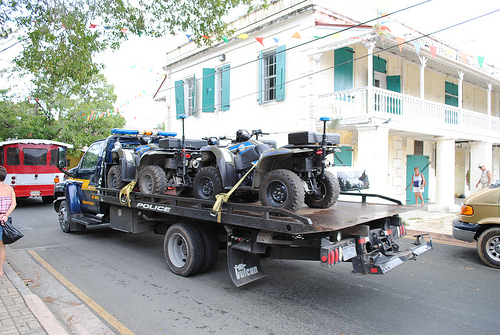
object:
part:
[177, 232, 191, 262]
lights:
[111, 128, 178, 137]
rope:
[211, 161, 259, 223]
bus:
[0, 138, 73, 204]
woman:
[0, 165, 22, 275]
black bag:
[2, 222, 24, 244]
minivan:
[447, 181, 500, 269]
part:
[406, 129, 426, 143]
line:
[23, 250, 134, 335]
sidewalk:
[0, 265, 66, 335]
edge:
[3, 251, 59, 330]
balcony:
[316, 53, 500, 142]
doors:
[202, 64, 230, 114]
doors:
[258, 44, 286, 105]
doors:
[174, 73, 196, 120]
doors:
[333, 46, 354, 104]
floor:
[233, 104, 353, 129]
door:
[406, 154, 430, 204]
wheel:
[257, 168, 303, 215]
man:
[410, 166, 427, 207]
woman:
[409, 167, 426, 207]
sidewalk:
[399, 196, 460, 236]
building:
[161, 1, 500, 209]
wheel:
[162, 222, 219, 277]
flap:
[226, 235, 268, 288]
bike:
[192, 117, 341, 213]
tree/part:
[23, 42, 91, 119]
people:
[475, 163, 491, 188]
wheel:
[58, 201, 86, 233]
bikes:
[106, 114, 206, 202]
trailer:
[52, 115, 434, 288]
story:
[153, 0, 500, 207]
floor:
[335, 49, 481, 109]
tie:
[212, 193, 229, 212]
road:
[0, 200, 500, 335]